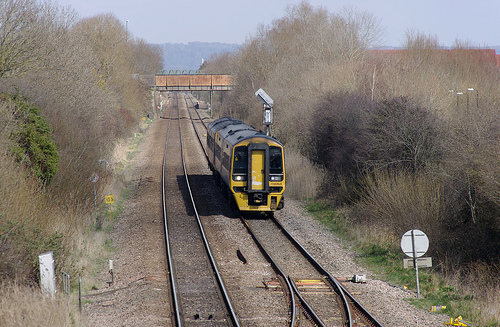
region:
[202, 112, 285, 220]
yellow train on tracks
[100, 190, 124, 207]
sign on side of road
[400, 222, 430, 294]
back of a sign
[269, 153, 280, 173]
right back window on train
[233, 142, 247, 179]
left window on train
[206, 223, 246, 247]
gravel on the train tracks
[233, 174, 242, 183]
light on back of train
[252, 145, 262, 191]
door on back of train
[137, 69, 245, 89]
overpass over train tracks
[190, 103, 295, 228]
black and yellow train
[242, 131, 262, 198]
yellow door on train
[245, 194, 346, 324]
train on grey track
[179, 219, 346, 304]
grey gravel between tracks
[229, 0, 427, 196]
bare trees behind train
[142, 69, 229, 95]
tan bridge behind train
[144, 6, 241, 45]
blue and white sky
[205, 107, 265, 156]
top of train is black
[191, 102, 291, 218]
train on the tracks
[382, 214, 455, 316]
sign for a train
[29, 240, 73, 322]
electric box in the grass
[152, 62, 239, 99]
bridge above the tracks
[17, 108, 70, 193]
green leaves of a tree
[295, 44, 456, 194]
dead trees along side of tracks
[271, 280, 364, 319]
switch in the train tracks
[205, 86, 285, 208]
yellow and black train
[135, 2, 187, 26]
white clouds in blue sky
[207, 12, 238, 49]
white clouds in blue sky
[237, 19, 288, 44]
white clouds in blue sky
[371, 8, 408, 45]
white clouds in blue sky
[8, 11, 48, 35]
white clouds in blue sky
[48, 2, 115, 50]
white clouds in blue sky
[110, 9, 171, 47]
white clouds in blue sky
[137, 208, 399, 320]
tracks for the train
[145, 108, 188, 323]
rail of the tracks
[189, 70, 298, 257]
train on the tracks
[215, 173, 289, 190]
light's on the train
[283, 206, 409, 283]
grass by the tracks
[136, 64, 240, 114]
bridge over the tracks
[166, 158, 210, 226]
shadow of the train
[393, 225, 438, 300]
back of traffic sign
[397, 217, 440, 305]
back of traffic sign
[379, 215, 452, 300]
back of traffic sign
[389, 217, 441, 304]
back of traffic sign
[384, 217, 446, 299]
back of traffic sign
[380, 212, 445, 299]
back of traffic sign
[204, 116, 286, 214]
black and yellow train on the tracks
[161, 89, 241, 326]
empty tracks next to the train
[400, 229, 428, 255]
the round sign facing away from the camera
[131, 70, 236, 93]
the bridge above train tracks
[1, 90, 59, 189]
the green tree on the left from the tracks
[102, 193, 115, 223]
the yellow sign on the left from tracks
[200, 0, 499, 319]
brown leafless trees on the right from the train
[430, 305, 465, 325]
yellow items on the ground near the sign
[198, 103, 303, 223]
black and yellow train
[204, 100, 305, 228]
black and yellow train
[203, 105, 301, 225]
black and yellow train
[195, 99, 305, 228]
black and yellow train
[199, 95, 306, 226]
black and yellow train